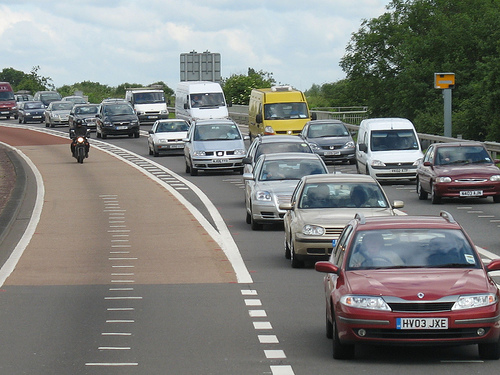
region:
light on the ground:
[63, 180, 183, 257]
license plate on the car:
[396, 319, 443, 331]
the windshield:
[358, 231, 456, 263]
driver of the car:
[348, 237, 395, 267]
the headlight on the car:
[341, 292, 383, 312]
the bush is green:
[391, 20, 466, 59]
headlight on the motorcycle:
[76, 133, 83, 141]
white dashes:
[238, 284, 295, 372]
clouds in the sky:
[93, 8, 180, 57]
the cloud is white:
[42, 10, 120, 49]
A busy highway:
[12, 14, 483, 339]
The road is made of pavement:
[32, 275, 297, 368]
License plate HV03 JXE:
[390, 306, 458, 335]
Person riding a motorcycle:
[53, 108, 111, 173]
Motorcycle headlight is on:
[70, 135, 89, 147]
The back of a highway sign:
[170, 44, 234, 86]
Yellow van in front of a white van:
[173, 67, 315, 136]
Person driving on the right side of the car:
[345, 221, 407, 277]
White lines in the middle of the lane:
[80, 176, 149, 373]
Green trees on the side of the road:
[327, 30, 496, 132]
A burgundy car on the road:
[315, 213, 498, 359]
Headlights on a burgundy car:
[337, 290, 497, 312]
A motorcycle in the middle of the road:
[65, 115, 94, 165]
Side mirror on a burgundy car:
[313, 259, 343, 276]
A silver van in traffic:
[182, 117, 247, 175]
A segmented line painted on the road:
[236, 277, 298, 373]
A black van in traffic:
[93, 96, 143, 139]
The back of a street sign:
[178, 50, 224, 87]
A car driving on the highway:
[416, 139, 499, 201]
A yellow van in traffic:
[248, 83, 318, 145]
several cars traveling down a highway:
[6, 45, 489, 350]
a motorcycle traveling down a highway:
[66, 108, 123, 183]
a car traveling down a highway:
[318, 210, 498, 357]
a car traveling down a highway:
[278, 169, 405, 264]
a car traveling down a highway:
[246, 155, 327, 217]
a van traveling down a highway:
[185, 111, 246, 176]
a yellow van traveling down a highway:
[240, 82, 315, 145]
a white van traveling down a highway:
[174, 75, 231, 126]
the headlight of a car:
[345, 293, 393, 312]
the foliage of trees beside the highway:
[335, 3, 499, 140]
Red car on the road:
[318, 205, 498, 360]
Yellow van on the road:
[241, 81, 321, 140]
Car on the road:
[279, 174, 404, 271]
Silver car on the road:
[240, 148, 340, 230]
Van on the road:
[182, 113, 250, 176]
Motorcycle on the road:
[63, 113, 97, 165]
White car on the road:
[145, 114, 203, 156]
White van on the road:
[119, 87, 171, 122]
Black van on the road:
[97, 95, 141, 140]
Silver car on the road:
[41, 98, 81, 128]